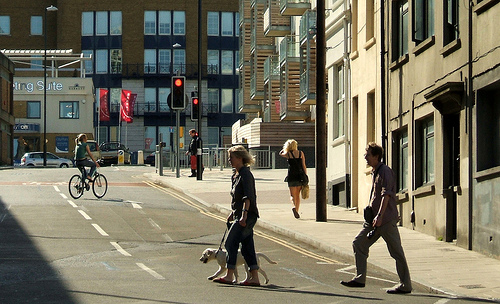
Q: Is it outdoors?
A: Yes, it is outdoors.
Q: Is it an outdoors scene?
A: Yes, it is outdoors.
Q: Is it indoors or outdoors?
A: It is outdoors.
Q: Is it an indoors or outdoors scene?
A: It is outdoors.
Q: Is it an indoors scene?
A: No, it is outdoors.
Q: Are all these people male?
A: No, they are both male and female.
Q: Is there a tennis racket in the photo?
A: No, there are no rackets.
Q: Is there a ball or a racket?
A: No, there are no rackets or balls.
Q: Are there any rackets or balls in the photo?
A: No, there are no rackets or balls.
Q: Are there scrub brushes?
A: No, there are no scrub brushes.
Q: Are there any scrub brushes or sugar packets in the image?
A: No, there are no scrub brushes or sugar packets.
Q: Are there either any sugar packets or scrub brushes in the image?
A: No, there are no scrub brushes or sugar packets.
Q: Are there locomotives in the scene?
A: No, there are no locomotives.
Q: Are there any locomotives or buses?
A: No, there are no locomotives or buses.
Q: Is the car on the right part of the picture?
A: No, the car is on the left of the image.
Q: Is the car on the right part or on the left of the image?
A: The car is on the left of the image.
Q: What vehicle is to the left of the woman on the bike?
A: The vehicle is a car.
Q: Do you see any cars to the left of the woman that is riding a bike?
A: Yes, there is a car to the left of the woman.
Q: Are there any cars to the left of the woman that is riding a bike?
A: Yes, there is a car to the left of the woman.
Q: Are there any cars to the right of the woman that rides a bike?
A: No, the car is to the left of the woman.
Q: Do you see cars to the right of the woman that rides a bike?
A: No, the car is to the left of the woman.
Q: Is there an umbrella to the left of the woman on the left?
A: No, there is a car to the left of the woman.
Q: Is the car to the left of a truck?
A: No, the car is to the left of the woman.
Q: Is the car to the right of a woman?
A: No, the car is to the left of a woman.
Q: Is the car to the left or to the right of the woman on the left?
A: The car is to the left of the woman.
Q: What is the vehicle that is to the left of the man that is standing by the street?
A: The vehicle is a car.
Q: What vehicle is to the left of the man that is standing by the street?
A: The vehicle is a car.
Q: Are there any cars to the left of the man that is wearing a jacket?
A: Yes, there is a car to the left of the man.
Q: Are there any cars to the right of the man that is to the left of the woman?
A: No, the car is to the left of the man.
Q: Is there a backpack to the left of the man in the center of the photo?
A: No, there is a car to the left of the man.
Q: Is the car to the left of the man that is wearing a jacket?
A: Yes, the car is to the left of the man.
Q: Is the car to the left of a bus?
A: No, the car is to the left of the man.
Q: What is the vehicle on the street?
A: The vehicle is a car.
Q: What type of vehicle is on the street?
A: The vehicle is a car.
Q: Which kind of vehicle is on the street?
A: The vehicle is a car.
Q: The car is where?
A: The car is on the street.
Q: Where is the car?
A: The car is on the street.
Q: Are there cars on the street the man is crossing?
A: Yes, there is a car on the street.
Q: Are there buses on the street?
A: No, there is a car on the street.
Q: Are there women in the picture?
A: Yes, there is a woman.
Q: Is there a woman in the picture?
A: Yes, there is a woman.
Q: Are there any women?
A: Yes, there is a woman.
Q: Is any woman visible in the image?
A: Yes, there is a woman.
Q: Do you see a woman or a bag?
A: Yes, there is a woman.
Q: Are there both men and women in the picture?
A: Yes, there are both a woman and a man.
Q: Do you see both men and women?
A: Yes, there are both a woman and a man.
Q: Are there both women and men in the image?
A: Yes, there are both a woman and a man.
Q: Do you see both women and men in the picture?
A: Yes, there are both a woman and a man.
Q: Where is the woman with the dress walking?
A: The woman is walking on the sidewalk.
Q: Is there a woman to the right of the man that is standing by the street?
A: Yes, there is a woman to the right of the man.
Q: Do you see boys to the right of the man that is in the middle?
A: No, there is a woman to the right of the man.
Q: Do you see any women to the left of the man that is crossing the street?
A: Yes, there is a woman to the left of the man.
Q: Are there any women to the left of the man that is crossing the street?
A: Yes, there is a woman to the left of the man.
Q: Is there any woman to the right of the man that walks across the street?
A: No, the woman is to the left of the man.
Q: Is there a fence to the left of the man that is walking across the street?
A: No, there is a woman to the left of the man.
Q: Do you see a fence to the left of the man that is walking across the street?
A: No, there is a woman to the left of the man.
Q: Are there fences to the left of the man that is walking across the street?
A: No, there is a woman to the left of the man.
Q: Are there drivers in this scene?
A: No, there are no drivers.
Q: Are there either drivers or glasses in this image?
A: No, there are no drivers or glasses.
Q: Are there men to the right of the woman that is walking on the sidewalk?
A: Yes, there is a man to the right of the woman.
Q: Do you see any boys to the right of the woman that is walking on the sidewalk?
A: No, there is a man to the right of the woman.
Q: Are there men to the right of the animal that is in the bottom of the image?
A: Yes, there is a man to the right of the dog.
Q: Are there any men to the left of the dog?
A: No, the man is to the right of the dog.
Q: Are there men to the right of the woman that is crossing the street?
A: Yes, there is a man to the right of the woman.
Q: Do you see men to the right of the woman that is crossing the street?
A: Yes, there is a man to the right of the woman.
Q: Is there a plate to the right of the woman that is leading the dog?
A: No, there is a man to the right of the woman.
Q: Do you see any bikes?
A: Yes, there is a bike.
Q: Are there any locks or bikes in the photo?
A: Yes, there is a bike.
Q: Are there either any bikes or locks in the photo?
A: Yes, there is a bike.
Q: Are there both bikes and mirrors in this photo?
A: No, there is a bike but no mirrors.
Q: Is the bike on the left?
A: Yes, the bike is on the left of the image.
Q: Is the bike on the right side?
A: No, the bike is on the left of the image.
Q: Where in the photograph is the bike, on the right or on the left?
A: The bike is on the left of the image.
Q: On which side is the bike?
A: The bike is on the left of the image.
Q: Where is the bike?
A: The bike is on the street.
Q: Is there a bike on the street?
A: Yes, there is a bike on the street.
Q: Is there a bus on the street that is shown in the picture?
A: No, there is a bike on the street.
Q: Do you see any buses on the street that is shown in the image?
A: No, there is a bike on the street.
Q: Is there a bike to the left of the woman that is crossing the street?
A: Yes, there is a bike to the left of the woman.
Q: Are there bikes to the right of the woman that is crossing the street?
A: No, the bike is to the left of the woman.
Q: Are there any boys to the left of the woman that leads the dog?
A: No, there is a bike to the left of the woman.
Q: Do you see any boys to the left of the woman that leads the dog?
A: No, there is a bike to the left of the woman.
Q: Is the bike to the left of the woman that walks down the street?
A: Yes, the bike is to the left of the woman.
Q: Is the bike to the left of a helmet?
A: No, the bike is to the left of the woman.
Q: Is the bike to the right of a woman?
A: No, the bike is to the left of a woman.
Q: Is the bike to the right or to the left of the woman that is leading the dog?
A: The bike is to the left of the woman.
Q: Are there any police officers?
A: No, there are no police officers.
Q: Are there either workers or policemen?
A: No, there are no policemen or workers.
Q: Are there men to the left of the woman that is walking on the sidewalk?
A: Yes, there is a man to the left of the woman.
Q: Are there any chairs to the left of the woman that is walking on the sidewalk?
A: No, there is a man to the left of the woman.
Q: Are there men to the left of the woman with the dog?
A: Yes, there is a man to the left of the woman.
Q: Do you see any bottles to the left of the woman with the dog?
A: No, there is a man to the left of the woman.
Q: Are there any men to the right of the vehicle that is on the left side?
A: Yes, there is a man to the right of the car.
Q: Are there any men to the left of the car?
A: No, the man is to the right of the car.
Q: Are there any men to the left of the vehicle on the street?
A: No, the man is to the right of the car.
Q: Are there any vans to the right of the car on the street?
A: No, there is a man to the right of the car.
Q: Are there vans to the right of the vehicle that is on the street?
A: No, there is a man to the right of the car.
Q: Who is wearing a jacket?
A: The man is wearing a jacket.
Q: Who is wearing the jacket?
A: The man is wearing a jacket.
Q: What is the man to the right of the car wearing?
A: The man is wearing a jacket.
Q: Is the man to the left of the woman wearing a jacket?
A: Yes, the man is wearing a jacket.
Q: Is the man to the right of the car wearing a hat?
A: No, the man is wearing a jacket.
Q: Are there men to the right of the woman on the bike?
A: Yes, there is a man to the right of the woman.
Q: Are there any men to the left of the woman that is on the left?
A: No, the man is to the right of the woman.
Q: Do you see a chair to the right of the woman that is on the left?
A: No, there is a man to the right of the woman.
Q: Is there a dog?
A: Yes, there is a dog.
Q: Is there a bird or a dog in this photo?
A: Yes, there is a dog.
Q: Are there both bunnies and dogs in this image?
A: No, there is a dog but no bunnies.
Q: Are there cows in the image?
A: No, there are no cows.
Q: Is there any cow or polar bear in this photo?
A: No, there are no cows or polar bears.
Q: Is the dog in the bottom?
A: Yes, the dog is in the bottom of the image.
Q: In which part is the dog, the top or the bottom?
A: The dog is in the bottom of the image.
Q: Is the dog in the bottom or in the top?
A: The dog is in the bottom of the image.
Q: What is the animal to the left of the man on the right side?
A: The animal is a dog.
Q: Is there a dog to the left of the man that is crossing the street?
A: Yes, there is a dog to the left of the man.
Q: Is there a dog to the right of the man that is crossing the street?
A: No, the dog is to the left of the man.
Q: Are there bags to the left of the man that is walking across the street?
A: No, there is a dog to the left of the man.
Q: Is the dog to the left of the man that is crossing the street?
A: Yes, the dog is to the left of the man.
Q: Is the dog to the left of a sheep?
A: No, the dog is to the left of the man.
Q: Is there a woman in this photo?
A: Yes, there is a woman.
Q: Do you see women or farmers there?
A: Yes, there is a woman.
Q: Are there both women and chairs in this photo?
A: No, there is a woman but no chairs.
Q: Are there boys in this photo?
A: No, there are no boys.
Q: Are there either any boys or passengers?
A: No, there are no boys or passengers.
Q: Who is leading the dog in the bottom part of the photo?
A: The woman is leading the dog.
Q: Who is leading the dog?
A: The woman is leading the dog.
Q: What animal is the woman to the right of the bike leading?
A: The woman is leading the dog.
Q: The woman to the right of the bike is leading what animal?
A: The woman is leading the dog.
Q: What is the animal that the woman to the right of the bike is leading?
A: The animal is a dog.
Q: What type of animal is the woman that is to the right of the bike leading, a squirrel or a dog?
A: The woman is leading a dog.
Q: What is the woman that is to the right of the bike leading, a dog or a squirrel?
A: The woman is leading a dog.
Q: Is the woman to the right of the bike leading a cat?
A: No, the woman is leading the dog.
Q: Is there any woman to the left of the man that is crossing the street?
A: Yes, there is a woman to the left of the man.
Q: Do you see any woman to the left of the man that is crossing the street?
A: Yes, there is a woman to the left of the man.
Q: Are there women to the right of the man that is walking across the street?
A: No, the woman is to the left of the man.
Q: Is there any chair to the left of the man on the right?
A: No, there is a woman to the left of the man.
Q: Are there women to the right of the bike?
A: Yes, there is a woman to the right of the bike.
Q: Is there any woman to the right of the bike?
A: Yes, there is a woman to the right of the bike.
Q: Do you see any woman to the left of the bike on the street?
A: No, the woman is to the right of the bike.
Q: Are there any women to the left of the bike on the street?
A: No, the woman is to the right of the bike.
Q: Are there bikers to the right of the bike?
A: No, there is a woman to the right of the bike.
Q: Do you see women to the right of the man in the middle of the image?
A: Yes, there is a woman to the right of the man.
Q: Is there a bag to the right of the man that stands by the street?
A: No, there is a woman to the right of the man.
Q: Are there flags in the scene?
A: Yes, there is a flag.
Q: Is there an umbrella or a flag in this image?
A: Yes, there is a flag.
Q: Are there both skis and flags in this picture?
A: No, there is a flag but no skis.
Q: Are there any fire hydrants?
A: No, there are no fire hydrants.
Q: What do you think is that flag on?
A: The flag is on the pole.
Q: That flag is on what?
A: The flag is on the pole.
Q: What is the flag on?
A: The flag is on the pole.